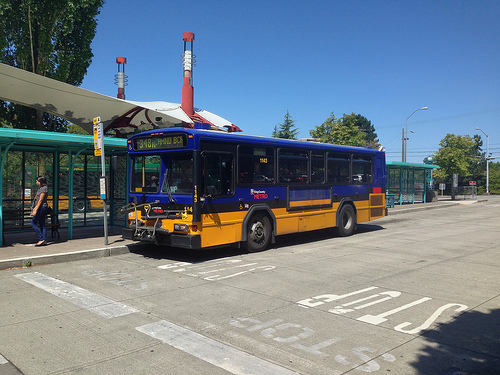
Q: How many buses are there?
A: One.